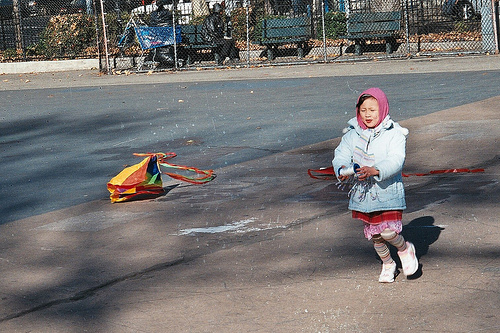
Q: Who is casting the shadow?
A: Little girl.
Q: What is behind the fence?
A: Green benches.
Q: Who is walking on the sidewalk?
A: Little girl.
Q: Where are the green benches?
A: Behind the fence.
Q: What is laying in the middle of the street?
A: Kite.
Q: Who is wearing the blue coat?
A: Child.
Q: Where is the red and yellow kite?
A: On the ground.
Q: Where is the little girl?
A: In the road.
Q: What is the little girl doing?
A: Running on the road.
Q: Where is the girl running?
A: In the street.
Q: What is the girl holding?
A: A kite.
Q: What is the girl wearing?
A: A blue jacket.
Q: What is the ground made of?
A: Asphalt.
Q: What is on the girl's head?
A: A hood.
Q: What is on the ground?
A: A kite.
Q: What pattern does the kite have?
A: Rainbow.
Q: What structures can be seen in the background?
A: Benches.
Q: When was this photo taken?
A: During the daytime.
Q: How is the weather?
A: Sunny.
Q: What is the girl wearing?
A: White jacket.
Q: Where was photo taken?
A: A park.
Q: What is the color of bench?
A: Green.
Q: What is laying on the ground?
A: A kite.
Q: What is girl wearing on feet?
A: White and pink tennis shoes.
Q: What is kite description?
A: Red, orange and green.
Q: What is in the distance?
A: A tall fence.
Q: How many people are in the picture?
A: One.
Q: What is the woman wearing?
A: A jacket.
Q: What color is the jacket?
A: Blue.